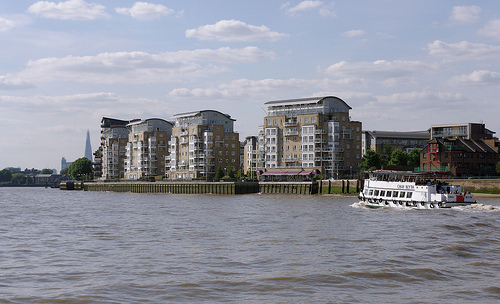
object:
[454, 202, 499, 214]
waves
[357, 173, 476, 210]
boat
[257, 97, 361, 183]
apartment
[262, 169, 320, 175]
awning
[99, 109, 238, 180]
building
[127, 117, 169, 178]
sky scraper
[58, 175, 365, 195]
boat dock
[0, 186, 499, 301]
river